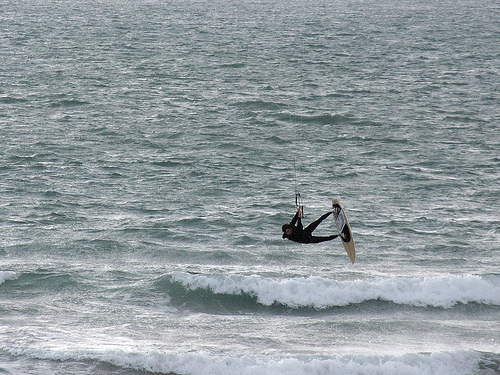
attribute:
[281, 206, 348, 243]
person — a young man, kite surfing, surf boarding, in the air, wearing black, wind surfing, para sailing, in photo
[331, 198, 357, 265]
surfboard — white, yellow, tan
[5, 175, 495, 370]
waves — white, green, crashing down, breaking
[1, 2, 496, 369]
water — the ocean, calm, foamy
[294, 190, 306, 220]
handle — to the kite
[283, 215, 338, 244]
wetsuit — black, black color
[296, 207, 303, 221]
hands — white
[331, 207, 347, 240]
feet — strapped in